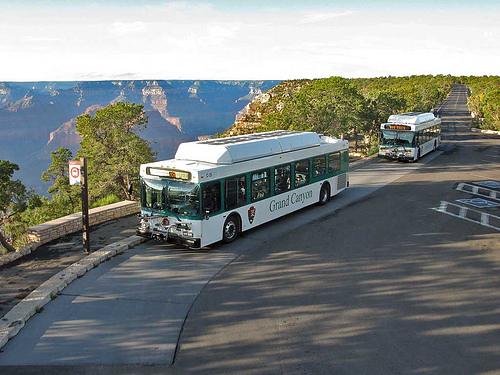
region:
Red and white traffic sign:
[63, 155, 85, 189]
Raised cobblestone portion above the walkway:
[32, 205, 137, 229]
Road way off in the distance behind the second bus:
[453, 86, 466, 126]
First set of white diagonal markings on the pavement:
[437, 210, 499, 217]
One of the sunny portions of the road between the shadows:
[223, 324, 299, 342]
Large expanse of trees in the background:
[299, 87, 389, 122]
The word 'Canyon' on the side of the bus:
[288, 186, 316, 203]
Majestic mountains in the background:
[151, 88, 236, 123]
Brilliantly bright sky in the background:
[69, 15, 413, 66]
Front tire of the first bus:
[219, 213, 246, 246]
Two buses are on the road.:
[132, 95, 442, 250]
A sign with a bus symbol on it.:
[55, 150, 105, 256]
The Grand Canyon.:
[5, 30, 320, 131]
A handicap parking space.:
[452, 182, 497, 217]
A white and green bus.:
[135, 130, 355, 245]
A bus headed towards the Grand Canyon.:
[130, 131, 365, 242]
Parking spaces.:
[427, 130, 493, 270]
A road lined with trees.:
[430, 75, 475, 135]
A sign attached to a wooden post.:
[60, 150, 105, 265]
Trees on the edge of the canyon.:
[1, 96, 142, 207]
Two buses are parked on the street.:
[134, 99, 451, 256]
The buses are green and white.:
[124, 95, 457, 254]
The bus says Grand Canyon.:
[259, 185, 319, 220]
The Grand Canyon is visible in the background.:
[0, 79, 277, 189]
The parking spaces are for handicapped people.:
[452, 168, 498, 213]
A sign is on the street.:
[64, 154, 101, 259]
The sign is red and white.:
[59, 149, 88, 191]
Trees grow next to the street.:
[0, 95, 162, 243]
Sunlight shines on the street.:
[123, 247, 498, 359]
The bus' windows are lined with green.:
[140, 150, 351, 221]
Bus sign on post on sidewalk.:
[63, 156, 96, 258]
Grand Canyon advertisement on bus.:
[266, 190, 318, 217]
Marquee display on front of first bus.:
[145, 165, 195, 182]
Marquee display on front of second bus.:
[382, 123, 412, 132]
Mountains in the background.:
[2, 83, 248, 118]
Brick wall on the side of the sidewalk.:
[32, 197, 139, 242]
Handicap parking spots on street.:
[436, 176, 498, 230]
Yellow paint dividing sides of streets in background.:
[447, 85, 464, 123]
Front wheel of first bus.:
[218, 216, 250, 242]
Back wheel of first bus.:
[313, 178, 335, 206]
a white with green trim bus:
[137, 123, 353, 249]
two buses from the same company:
[129, 111, 442, 252]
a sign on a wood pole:
[67, 156, 94, 256]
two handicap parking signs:
[440, 178, 497, 233]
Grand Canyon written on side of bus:
[266, 185, 318, 212]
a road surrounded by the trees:
[427, 78, 487, 168]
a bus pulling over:
[111, 124, 372, 267]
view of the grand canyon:
[7, 93, 270, 221]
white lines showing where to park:
[432, 174, 497, 245]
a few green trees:
[22, 120, 157, 237]